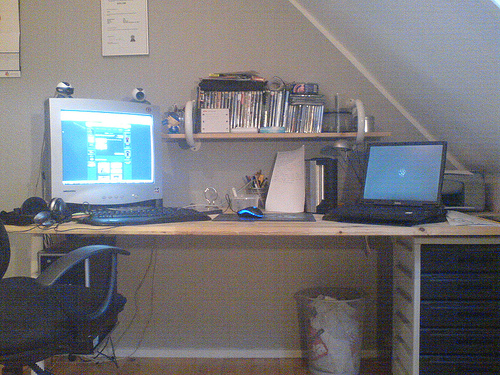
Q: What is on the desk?
A: Laptop.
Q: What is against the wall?
A: Trash can.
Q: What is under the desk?
A: Drawers.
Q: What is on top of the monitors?
A: Webcams.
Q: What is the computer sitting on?
A: Desk.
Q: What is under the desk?
A: Trash bin.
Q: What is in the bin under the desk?
A: Trash.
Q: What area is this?
A: Home office.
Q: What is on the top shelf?
A: CDs.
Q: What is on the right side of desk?
A: Laptop.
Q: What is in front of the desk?
A: Chair.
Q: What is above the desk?
A: Shelf.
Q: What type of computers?
A: Laptop.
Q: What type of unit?
A: Drawer.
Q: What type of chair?
A: Office.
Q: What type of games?
A: Video games.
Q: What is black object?
A: Chair.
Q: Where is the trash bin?
A: On ground.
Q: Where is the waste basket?
A: Under the desk.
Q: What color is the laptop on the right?
A: Black.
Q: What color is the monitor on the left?
A: Silver.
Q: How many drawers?
A: 5.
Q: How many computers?
A: 2.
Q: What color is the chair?
A: Black.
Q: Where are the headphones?
A: By the monitor.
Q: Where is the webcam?
A: On top of the monitor.